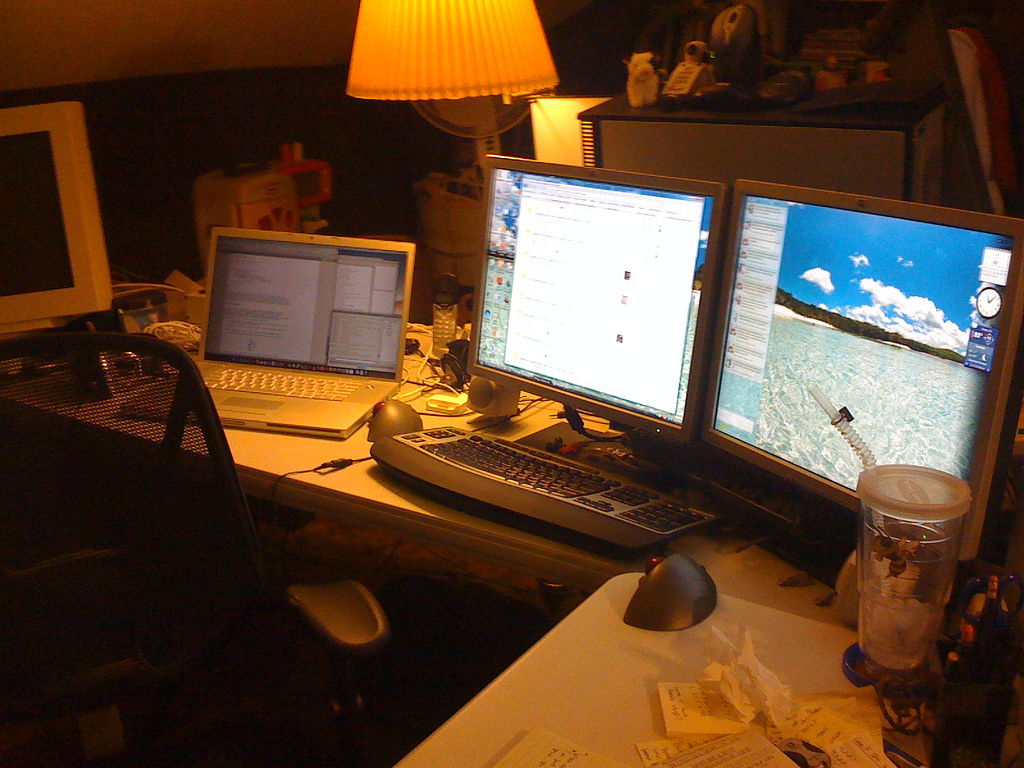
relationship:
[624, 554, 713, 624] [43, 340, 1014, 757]
mouse on desk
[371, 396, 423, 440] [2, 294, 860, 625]
mouse on desk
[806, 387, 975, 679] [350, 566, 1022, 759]
cup on desk